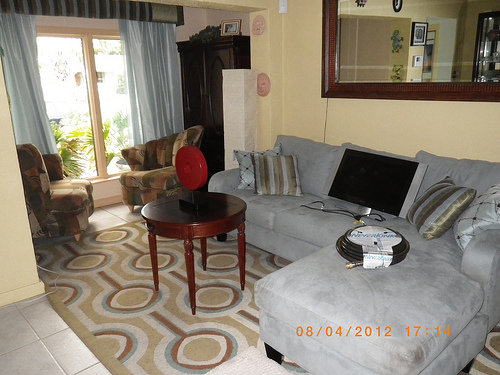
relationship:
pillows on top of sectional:
[228, 142, 499, 248] [207, 132, 499, 374]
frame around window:
[33, 26, 130, 183] [93, 36, 134, 175]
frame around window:
[33, 26, 130, 183] [35, 36, 98, 180]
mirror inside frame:
[336, 1, 499, 80] [320, 0, 499, 102]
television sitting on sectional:
[326, 145, 428, 222] [207, 132, 499, 374]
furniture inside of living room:
[17, 36, 499, 374] [1, 0, 499, 374]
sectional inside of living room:
[207, 132, 499, 374] [1, 0, 499, 374]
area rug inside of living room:
[31, 216, 293, 374] [1, 0, 499, 374]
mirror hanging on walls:
[336, 1, 499, 80] [214, 0, 498, 164]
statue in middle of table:
[174, 144, 210, 212] [142, 188, 247, 311]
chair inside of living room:
[118, 124, 206, 211] [1, 0, 499, 374]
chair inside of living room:
[16, 142, 94, 238] [1, 0, 499, 374]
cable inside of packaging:
[335, 223, 409, 272] [348, 223, 401, 268]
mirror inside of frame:
[336, 1, 499, 80] [320, 0, 499, 102]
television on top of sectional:
[326, 145, 428, 222] [207, 132, 499, 374]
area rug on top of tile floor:
[31, 216, 293, 374] [1, 200, 144, 374]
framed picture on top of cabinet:
[217, 17, 243, 37] [174, 35, 251, 191]